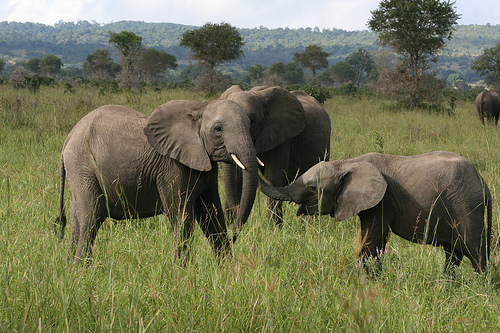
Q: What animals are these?
A: Elephants.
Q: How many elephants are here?
A: 3.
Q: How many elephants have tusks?
A: 1.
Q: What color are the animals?
A: Gray.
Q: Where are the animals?
A: Grassy field.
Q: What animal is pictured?
A: Elephants.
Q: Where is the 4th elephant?
A: In the distance to the right.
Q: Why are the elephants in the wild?
A: That is their natural habitat.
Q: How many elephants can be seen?
A: There are 4.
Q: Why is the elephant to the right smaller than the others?
A: It is a baby elephant.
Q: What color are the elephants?
A: Grey.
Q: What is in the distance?
A: A forest.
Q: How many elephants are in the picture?
A: 3.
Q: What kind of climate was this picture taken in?
A: Savanna.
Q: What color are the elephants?
A: Grey.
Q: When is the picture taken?
A: Daytime.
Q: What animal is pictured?
A: Elephants.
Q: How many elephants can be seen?
A: 4.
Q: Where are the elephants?
A: In the grass.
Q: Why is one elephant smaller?
A: It's a baby.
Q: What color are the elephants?
A: Gray.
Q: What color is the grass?
A: Green.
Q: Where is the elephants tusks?
A: On either side of its trunk.